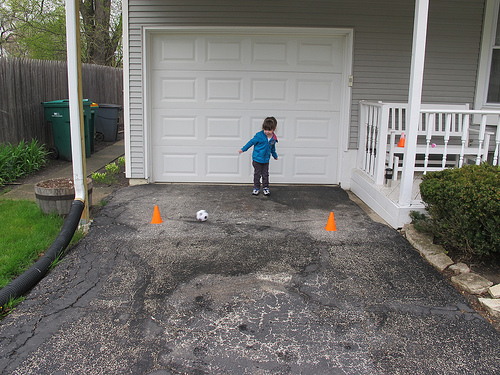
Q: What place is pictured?
A: It is a garage.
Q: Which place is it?
A: It is a garage.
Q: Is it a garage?
A: Yes, it is a garage.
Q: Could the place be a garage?
A: Yes, it is a garage.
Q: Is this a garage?
A: Yes, it is a garage.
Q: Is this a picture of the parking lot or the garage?
A: It is showing the garage.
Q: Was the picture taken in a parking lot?
A: No, the picture was taken in a garage.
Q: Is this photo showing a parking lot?
A: No, the picture is showing a garage.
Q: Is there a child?
A: Yes, there is a child.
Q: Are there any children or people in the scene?
A: Yes, there is a child.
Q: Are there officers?
A: No, there are no officers.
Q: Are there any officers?
A: No, there are no officers.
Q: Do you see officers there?
A: No, there are no officers.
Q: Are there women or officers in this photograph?
A: No, there are no officers or women.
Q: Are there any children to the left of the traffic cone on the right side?
A: Yes, there is a child to the left of the cone.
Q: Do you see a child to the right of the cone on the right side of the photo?
A: No, the child is to the left of the cone.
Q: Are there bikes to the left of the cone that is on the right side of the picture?
A: No, there is a child to the left of the safety cone.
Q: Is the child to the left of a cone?
A: Yes, the child is to the left of a cone.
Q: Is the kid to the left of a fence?
A: No, the kid is to the left of a cone.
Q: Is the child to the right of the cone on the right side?
A: No, the child is to the left of the safety cone.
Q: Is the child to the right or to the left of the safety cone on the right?
A: The child is to the left of the traffic cone.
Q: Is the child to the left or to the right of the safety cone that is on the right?
A: The child is to the left of the traffic cone.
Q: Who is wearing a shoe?
A: The kid is wearing a shoe.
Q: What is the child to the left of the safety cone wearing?
A: The kid is wearing a shoe.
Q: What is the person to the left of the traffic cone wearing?
A: The kid is wearing a shoe.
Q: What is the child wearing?
A: The kid is wearing a shoe.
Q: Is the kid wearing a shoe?
A: Yes, the kid is wearing a shoe.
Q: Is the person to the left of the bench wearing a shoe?
A: Yes, the kid is wearing a shoe.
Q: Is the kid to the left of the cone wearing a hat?
A: No, the child is wearing a shoe.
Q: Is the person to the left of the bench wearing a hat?
A: No, the child is wearing a shoe.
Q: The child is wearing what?
A: The child is wearing a shoe.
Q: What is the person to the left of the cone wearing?
A: The child is wearing a shoe.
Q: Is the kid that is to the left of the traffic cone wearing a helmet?
A: No, the kid is wearing a shoe.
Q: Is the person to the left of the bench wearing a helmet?
A: No, the kid is wearing a shoe.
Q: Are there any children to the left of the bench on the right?
A: Yes, there is a child to the left of the bench.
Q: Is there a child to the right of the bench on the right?
A: No, the child is to the left of the bench.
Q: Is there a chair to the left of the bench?
A: No, there is a child to the left of the bench.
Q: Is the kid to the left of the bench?
A: Yes, the kid is to the left of the bench.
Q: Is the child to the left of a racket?
A: No, the child is to the left of the bench.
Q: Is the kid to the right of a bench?
A: No, the kid is to the left of a bench.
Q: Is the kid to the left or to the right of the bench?
A: The kid is to the left of the bench.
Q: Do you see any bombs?
A: No, there are no bombs.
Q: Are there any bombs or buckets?
A: No, there are no bombs or buckets.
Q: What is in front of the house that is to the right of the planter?
A: The shrub is in front of the house.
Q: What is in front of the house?
A: The shrub is in front of the house.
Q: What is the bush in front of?
A: The bush is in front of the house.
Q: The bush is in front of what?
A: The bush is in front of the house.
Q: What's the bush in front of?
A: The bush is in front of the house.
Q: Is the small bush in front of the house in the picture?
A: Yes, the bush is in front of the house.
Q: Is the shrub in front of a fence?
A: No, the shrub is in front of the house.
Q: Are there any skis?
A: No, there are no skis.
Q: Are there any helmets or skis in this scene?
A: No, there are no skis or helmets.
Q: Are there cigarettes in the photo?
A: No, there are no cigarettes.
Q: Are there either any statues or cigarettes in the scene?
A: No, there are no cigarettes or statues.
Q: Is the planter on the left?
A: Yes, the planter is on the left of the image.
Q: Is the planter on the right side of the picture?
A: No, the planter is on the left of the image.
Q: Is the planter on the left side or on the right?
A: The planter is on the left of the image.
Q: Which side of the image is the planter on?
A: The planter is on the left of the image.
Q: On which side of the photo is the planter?
A: The planter is on the left of the image.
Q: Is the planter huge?
A: Yes, the planter is huge.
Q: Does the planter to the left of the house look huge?
A: Yes, the planter is huge.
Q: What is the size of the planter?
A: The planter is huge.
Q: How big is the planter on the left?
A: The planter is huge.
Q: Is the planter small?
A: No, the planter is huge.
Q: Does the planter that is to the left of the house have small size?
A: No, the planter is huge.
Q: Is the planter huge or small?
A: The planter is huge.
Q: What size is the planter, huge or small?
A: The planter is huge.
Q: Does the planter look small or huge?
A: The planter is huge.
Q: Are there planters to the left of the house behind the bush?
A: Yes, there is a planter to the left of the house.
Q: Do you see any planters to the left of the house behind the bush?
A: Yes, there is a planter to the left of the house.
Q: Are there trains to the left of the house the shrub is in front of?
A: No, there is a planter to the left of the house.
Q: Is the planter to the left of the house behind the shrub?
A: Yes, the planter is to the left of the house.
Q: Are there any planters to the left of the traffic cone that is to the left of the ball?
A: Yes, there is a planter to the left of the traffic cone.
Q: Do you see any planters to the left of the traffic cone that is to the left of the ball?
A: Yes, there is a planter to the left of the traffic cone.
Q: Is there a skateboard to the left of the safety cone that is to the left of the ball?
A: No, there is a planter to the left of the traffic cone.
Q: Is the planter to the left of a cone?
A: Yes, the planter is to the left of a cone.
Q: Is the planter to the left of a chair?
A: No, the planter is to the left of a cone.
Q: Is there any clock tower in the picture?
A: No, there are no clock towers.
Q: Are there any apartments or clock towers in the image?
A: No, there are no clock towers or apartments.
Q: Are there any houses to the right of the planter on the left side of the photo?
A: Yes, there is a house to the right of the planter.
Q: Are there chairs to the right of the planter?
A: No, there is a house to the right of the planter.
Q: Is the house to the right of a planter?
A: Yes, the house is to the right of a planter.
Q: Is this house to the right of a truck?
A: No, the house is to the right of a planter.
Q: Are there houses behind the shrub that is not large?
A: Yes, there is a house behind the shrub.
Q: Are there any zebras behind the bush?
A: No, there is a house behind the bush.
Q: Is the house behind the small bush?
A: Yes, the house is behind the bush.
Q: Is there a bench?
A: Yes, there is a bench.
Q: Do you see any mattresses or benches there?
A: Yes, there is a bench.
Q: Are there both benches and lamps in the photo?
A: No, there is a bench but no lamps.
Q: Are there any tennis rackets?
A: No, there are no tennis rackets.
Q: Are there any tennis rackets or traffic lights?
A: No, there are no tennis rackets or traffic lights.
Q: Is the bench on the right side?
A: Yes, the bench is on the right of the image.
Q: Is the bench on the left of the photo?
A: No, the bench is on the right of the image.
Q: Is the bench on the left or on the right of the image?
A: The bench is on the right of the image.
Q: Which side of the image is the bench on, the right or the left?
A: The bench is on the right of the image.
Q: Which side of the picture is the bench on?
A: The bench is on the right of the image.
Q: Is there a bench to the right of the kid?
A: Yes, there is a bench to the right of the kid.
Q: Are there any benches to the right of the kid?
A: Yes, there is a bench to the right of the kid.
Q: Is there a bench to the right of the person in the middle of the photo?
A: Yes, there is a bench to the right of the kid.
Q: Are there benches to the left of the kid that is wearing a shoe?
A: No, the bench is to the right of the child.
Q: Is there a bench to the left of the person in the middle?
A: No, the bench is to the right of the child.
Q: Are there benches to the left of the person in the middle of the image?
A: No, the bench is to the right of the child.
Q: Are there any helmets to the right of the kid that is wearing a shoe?
A: No, there is a bench to the right of the child.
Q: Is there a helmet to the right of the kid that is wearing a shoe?
A: No, there is a bench to the right of the child.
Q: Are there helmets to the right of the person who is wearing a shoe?
A: No, there is a bench to the right of the child.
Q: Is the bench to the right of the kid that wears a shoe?
A: Yes, the bench is to the right of the kid.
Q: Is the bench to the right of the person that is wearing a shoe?
A: Yes, the bench is to the right of the kid.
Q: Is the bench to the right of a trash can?
A: No, the bench is to the right of the kid.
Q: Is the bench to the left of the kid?
A: No, the bench is to the right of the kid.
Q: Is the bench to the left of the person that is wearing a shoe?
A: No, the bench is to the right of the kid.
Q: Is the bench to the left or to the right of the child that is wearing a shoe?
A: The bench is to the right of the child.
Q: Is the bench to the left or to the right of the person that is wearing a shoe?
A: The bench is to the right of the child.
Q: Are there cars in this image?
A: No, there are no cars.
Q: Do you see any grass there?
A: Yes, there is grass.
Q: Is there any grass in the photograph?
A: Yes, there is grass.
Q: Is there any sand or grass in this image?
A: Yes, there is grass.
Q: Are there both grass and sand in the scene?
A: No, there is grass but no sand.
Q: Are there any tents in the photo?
A: No, there are no tents.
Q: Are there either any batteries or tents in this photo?
A: No, there are no tents or batteries.